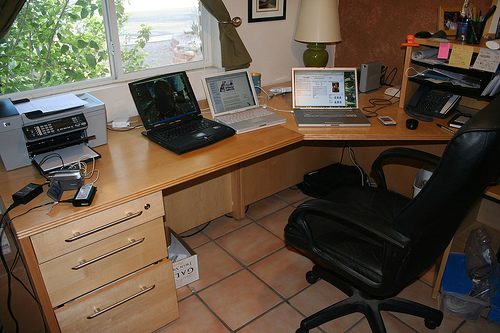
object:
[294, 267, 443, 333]
base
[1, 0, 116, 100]
window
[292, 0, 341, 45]
white shade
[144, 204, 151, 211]
lock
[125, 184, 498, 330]
tile flooring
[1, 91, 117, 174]
printer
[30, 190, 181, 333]
drawers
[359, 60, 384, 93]
modem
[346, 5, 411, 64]
wall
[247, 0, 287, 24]
picture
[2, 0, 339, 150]
wall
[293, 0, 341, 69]
lamp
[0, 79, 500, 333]
desk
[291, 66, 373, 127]
computer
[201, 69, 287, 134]
computer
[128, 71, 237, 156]
computer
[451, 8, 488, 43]
pen holder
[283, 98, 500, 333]
chair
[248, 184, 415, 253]
arms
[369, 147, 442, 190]
arms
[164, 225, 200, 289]
cardboard box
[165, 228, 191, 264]
trash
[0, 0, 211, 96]
window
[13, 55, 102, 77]
bush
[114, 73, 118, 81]
trim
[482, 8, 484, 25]
pencil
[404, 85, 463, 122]
phone